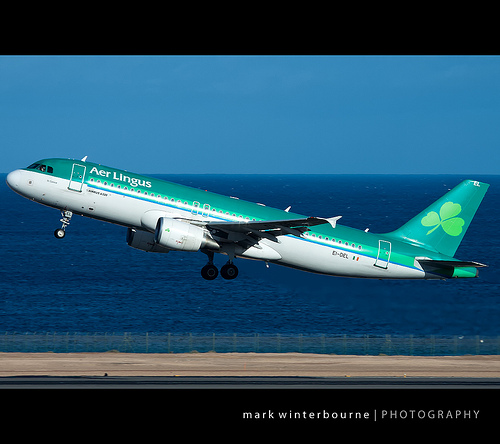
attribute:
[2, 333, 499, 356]
fence — short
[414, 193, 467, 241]
shamrock — light green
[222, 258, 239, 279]
wheel — down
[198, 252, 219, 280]
wheel — down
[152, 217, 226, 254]
engine — large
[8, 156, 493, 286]
plane — green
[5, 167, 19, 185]
nose — white, rounded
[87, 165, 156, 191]
letters — white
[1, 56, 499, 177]
sky — blue, clear